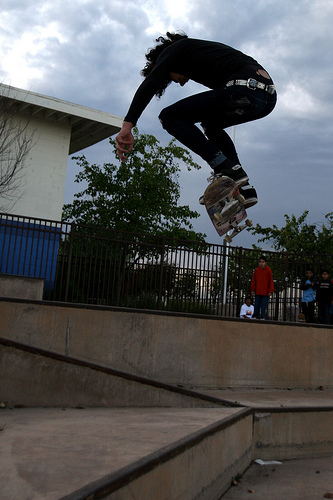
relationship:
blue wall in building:
[0, 216, 60, 284] [0, 81, 124, 301]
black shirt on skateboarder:
[122, 37, 274, 127] [111, 29, 277, 215]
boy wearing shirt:
[115, 36, 276, 209] [122, 37, 278, 125]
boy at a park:
[111, 32, 277, 210] [1, 94, 333, 496]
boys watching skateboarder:
[237, 254, 332, 325] [111, 29, 277, 215]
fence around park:
[3, 209, 332, 329] [1, 77, 320, 498]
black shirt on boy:
[124, 37, 275, 85] [115, 36, 276, 209]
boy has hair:
[115, 36, 276, 209] [149, 32, 177, 80]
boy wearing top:
[115, 36, 276, 209] [239, 303, 254, 317]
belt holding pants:
[234, 81, 278, 91] [159, 79, 277, 183]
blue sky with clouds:
[5, 1, 129, 103] [0, 0, 332, 250]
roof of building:
[1, 80, 126, 152] [0, 81, 124, 301]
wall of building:
[0, 115, 73, 298] [0, 81, 124, 301]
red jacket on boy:
[248, 263, 277, 296] [251, 255, 274, 319]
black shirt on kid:
[122, 37, 274, 127] [110, 30, 284, 240]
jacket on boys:
[299, 288, 315, 300] [299, 271, 317, 322]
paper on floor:
[250, 451, 289, 469] [215, 458, 318, 498]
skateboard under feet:
[203, 175, 252, 240] [195, 169, 263, 200]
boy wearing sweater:
[253, 253, 273, 319] [251, 264, 273, 293]